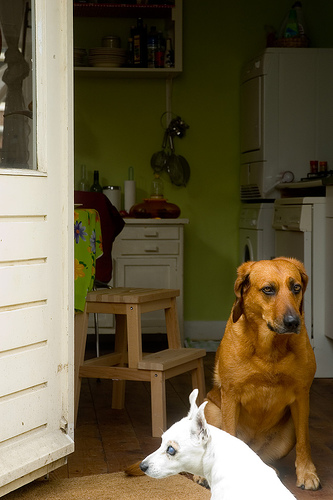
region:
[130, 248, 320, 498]
brown dog and white dog sitting together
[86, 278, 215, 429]
wooden step stool with two steps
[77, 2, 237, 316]
green wall in the kitchen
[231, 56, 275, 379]
white washer and dryer stacked on each other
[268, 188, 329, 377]
white oven behind brown dog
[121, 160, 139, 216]
paper towel holder on the counter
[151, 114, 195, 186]
strainers hanging on the wall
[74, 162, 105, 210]
two glass bottles on the countertop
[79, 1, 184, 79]
shelf above countertop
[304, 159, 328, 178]
two condiment bottles on the counter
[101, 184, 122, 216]
white cannister with silver lid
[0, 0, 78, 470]
white door next to dogs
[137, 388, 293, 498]
white dog with black nose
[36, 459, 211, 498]
light brown rug on the floor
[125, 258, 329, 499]
brown dog with brown eyes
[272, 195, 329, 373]
white oven with white door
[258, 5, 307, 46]
basket on top of washer and dryer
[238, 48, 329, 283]
washer and dryer stacked in the corner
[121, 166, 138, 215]
paper towel roll on holder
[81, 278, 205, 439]
step stool next to dogs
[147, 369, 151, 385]
edge of a bench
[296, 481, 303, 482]
part of a foot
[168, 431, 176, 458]
part of an eye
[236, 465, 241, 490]
back of a dog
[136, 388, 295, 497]
the dog is white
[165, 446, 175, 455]
the dog is blue eyes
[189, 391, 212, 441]
the dog has pointy ears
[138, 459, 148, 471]
the dog has a black nose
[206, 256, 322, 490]
the dog is brown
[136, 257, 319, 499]
the dogs are indoors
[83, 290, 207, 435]
the step stool is made of wood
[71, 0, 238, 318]
the wall is green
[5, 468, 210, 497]
the carpet is brown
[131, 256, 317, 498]
two dogs sitting down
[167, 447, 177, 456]
dog has clouded eyes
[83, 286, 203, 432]
a wooden step stool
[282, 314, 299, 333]
dog's nose is black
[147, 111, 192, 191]
pans hanging on the wall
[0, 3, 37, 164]
window on the door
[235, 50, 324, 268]
stackable washer and dryer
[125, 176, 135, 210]
a roll of paper towels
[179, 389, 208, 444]
the dog's ears are standing up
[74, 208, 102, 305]
a green and floral table cloth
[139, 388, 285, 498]
small white dog with pointy ears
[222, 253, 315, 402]
large light brown colored dog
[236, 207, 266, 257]
white front load washer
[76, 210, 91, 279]
neon green floral tablecloth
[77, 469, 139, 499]
brown shag rug next to dogs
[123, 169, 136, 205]
roll of paper towels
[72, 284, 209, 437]
step stool beside dog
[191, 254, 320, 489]
dog is sitting next to stool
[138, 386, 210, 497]
dog's ears are straight up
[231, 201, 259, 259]
washer behind the dog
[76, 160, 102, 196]
two bottles on the counter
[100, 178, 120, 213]
canister on the counter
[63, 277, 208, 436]
stool is made of wood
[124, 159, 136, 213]
paper towels on the counter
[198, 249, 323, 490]
dog is a golden tan color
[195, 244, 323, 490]
A dog is brown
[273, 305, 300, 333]
Black nose of a dog